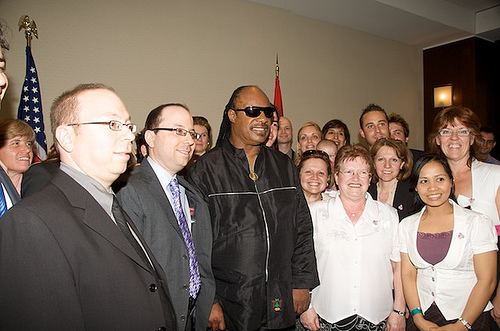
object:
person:
[297, 149, 335, 205]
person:
[294, 143, 406, 330]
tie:
[112, 194, 177, 330]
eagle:
[17, 14, 41, 39]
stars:
[32, 106, 40, 113]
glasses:
[243, 104, 276, 118]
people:
[397, 152, 499, 330]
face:
[235, 88, 277, 142]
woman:
[428, 105, 499, 238]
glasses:
[437, 127, 471, 136]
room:
[0, 2, 497, 162]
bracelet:
[410, 306, 424, 316]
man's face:
[72, 100, 137, 174]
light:
[432, 85, 457, 108]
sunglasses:
[303, 149, 331, 157]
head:
[297, 149, 335, 194]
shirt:
[398, 198, 499, 320]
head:
[143, 102, 198, 172]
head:
[224, 84, 277, 146]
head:
[49, 82, 138, 182]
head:
[357, 102, 393, 146]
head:
[473, 127, 500, 154]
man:
[470, 124, 499, 165]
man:
[274, 115, 297, 159]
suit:
[0, 168, 178, 330]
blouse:
[306, 191, 403, 325]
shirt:
[184, 133, 321, 330]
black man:
[185, 85, 321, 329]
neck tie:
[166, 177, 201, 299]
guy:
[0, 82, 179, 329]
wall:
[0, 14, 499, 159]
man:
[116, 102, 217, 330]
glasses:
[66, 119, 138, 133]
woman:
[367, 137, 418, 222]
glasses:
[337, 169, 371, 176]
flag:
[16, 45, 49, 161]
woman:
[0, 119, 38, 197]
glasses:
[152, 127, 198, 139]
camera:
[0, 0, 499, 330]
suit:
[115, 154, 217, 329]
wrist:
[389, 302, 407, 314]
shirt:
[376, 179, 398, 206]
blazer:
[366, 177, 427, 221]